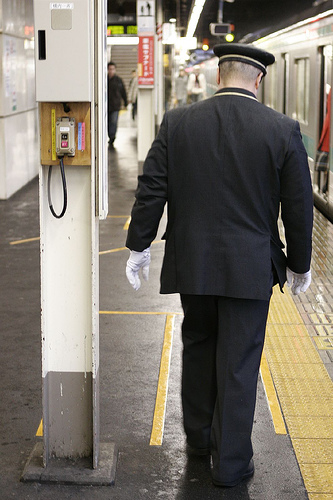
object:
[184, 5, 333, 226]
train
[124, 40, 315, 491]
conductor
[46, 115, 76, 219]
telephone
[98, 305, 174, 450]
markings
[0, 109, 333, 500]
platform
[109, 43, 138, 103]
stairs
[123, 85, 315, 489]
suit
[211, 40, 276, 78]
hat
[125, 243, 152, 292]
glove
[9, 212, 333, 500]
zone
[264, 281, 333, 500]
yellow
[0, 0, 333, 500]
subway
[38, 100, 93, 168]
box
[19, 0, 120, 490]
post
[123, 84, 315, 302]
jacket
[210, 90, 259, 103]
trim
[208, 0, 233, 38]
camera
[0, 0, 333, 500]
tunnel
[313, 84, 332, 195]
passeneger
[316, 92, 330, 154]
jacket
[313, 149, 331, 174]
skirt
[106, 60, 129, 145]
person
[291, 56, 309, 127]
window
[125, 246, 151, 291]
hand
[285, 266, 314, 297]
glove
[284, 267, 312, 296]
hand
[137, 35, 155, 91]
sign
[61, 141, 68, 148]
button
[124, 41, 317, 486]
unifrom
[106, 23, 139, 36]
sign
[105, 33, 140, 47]
door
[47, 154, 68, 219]
cord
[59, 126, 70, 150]
switch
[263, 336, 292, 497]
strip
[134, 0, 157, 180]
pole